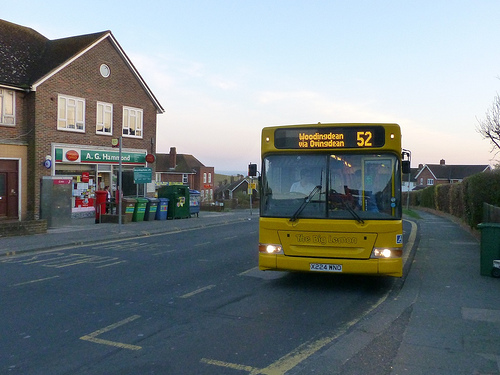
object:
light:
[266, 245, 281, 254]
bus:
[248, 123, 411, 281]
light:
[375, 249, 392, 257]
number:
[357, 131, 373, 146]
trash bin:
[122, 198, 137, 222]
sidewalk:
[0, 205, 261, 262]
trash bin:
[132, 197, 149, 222]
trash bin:
[145, 198, 160, 221]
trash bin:
[156, 198, 170, 220]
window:
[61, 100, 84, 129]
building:
[0, 18, 167, 236]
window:
[97, 101, 112, 134]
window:
[123, 109, 142, 136]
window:
[0, 91, 13, 123]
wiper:
[285, 168, 325, 218]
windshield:
[261, 154, 401, 219]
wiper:
[330, 170, 365, 223]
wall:
[0, 88, 28, 143]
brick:
[41, 123, 46, 128]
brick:
[124, 89, 128, 92]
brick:
[55, 75, 59, 78]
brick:
[142, 144, 147, 149]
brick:
[79, 66, 85, 71]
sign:
[247, 182, 256, 189]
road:
[0, 216, 420, 372]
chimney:
[169, 147, 176, 169]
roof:
[156, 153, 206, 173]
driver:
[286, 170, 317, 202]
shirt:
[289, 183, 324, 197]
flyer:
[74, 191, 86, 197]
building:
[414, 159, 492, 185]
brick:
[425, 172, 426, 177]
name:
[299, 132, 345, 147]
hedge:
[401, 170, 499, 228]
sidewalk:
[291, 209, 499, 373]